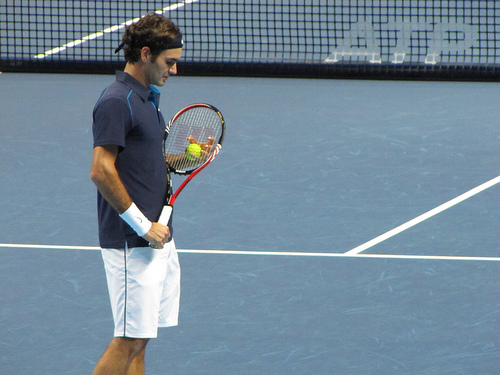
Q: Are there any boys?
A: No, there are no boys.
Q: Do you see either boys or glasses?
A: No, there are no boys or glasses.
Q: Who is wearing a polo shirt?
A: The man is wearing a polo shirt.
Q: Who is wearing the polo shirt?
A: The man is wearing a polo shirt.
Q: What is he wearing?
A: The man is wearing a polo shirt.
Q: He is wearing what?
A: The man is wearing a polo shirt.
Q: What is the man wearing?
A: The man is wearing a polo shirt.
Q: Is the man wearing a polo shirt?
A: Yes, the man is wearing a polo shirt.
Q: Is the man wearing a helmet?
A: No, the man is wearing a polo shirt.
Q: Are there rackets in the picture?
A: Yes, there is a racket.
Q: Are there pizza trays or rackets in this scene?
A: Yes, there is a racket.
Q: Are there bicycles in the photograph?
A: No, there are no bicycles.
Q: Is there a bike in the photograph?
A: No, there are no bikes.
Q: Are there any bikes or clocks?
A: No, there are no bikes or clocks.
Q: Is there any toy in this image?
A: No, there are no toys.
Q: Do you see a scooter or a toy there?
A: No, there are no toys or scooters.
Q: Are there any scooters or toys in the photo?
A: No, there are no toys or scooters.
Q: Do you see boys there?
A: No, there are no boys.